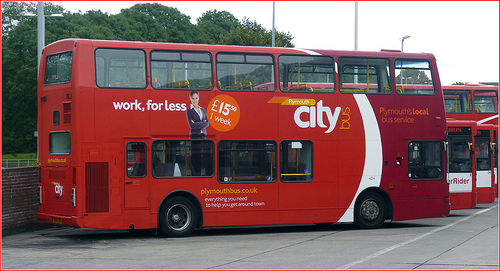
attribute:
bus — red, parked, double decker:
[34, 38, 452, 236]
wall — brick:
[1, 166, 38, 236]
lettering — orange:
[200, 185, 268, 208]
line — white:
[343, 204, 499, 270]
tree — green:
[0, 14, 91, 157]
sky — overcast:
[45, 3, 498, 83]